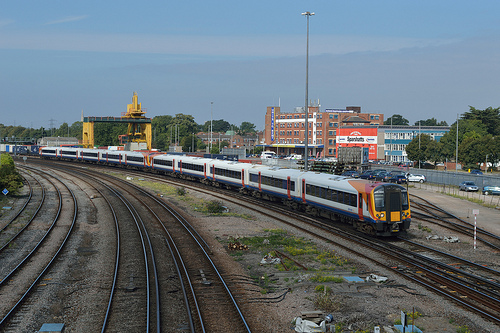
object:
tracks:
[7, 162, 219, 327]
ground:
[6, 177, 496, 333]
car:
[459, 181, 479, 192]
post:
[300, 11, 315, 171]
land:
[208, 192, 499, 332]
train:
[38, 146, 411, 237]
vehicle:
[481, 185, 497, 196]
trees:
[456, 123, 494, 171]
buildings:
[334, 125, 459, 162]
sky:
[0, 6, 305, 105]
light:
[302, 12, 316, 16]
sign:
[336, 127, 376, 163]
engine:
[298, 172, 411, 236]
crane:
[118, 90, 152, 149]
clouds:
[116, 31, 372, 60]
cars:
[408, 174, 426, 183]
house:
[265, 106, 336, 160]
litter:
[230, 229, 388, 284]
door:
[358, 193, 363, 220]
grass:
[127, 180, 251, 214]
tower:
[80, 109, 84, 122]